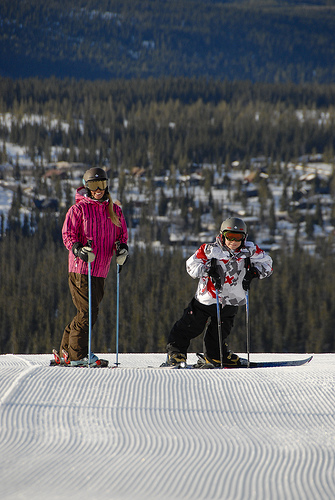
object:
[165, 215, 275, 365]
boy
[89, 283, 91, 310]
blue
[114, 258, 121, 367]
pole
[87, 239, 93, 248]
metal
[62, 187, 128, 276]
jacket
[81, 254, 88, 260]
black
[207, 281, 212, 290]
red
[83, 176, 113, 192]
goggles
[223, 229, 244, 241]
pair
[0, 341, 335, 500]
slopes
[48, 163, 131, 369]
mom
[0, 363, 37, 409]
lines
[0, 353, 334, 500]
snow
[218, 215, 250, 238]
helmets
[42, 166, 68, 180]
houses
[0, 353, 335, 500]
ground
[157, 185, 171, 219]
trees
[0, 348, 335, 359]
horizon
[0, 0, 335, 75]
mountain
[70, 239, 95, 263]
binding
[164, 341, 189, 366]
boot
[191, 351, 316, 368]
ski